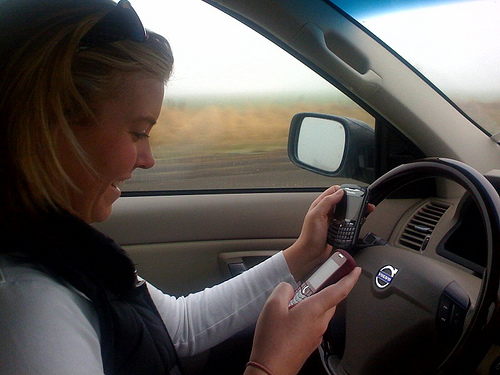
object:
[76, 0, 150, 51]
sunglasses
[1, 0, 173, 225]
head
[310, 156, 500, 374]
steering wheel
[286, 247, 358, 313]
phone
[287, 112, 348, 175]
mirror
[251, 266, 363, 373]
hand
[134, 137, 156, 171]
nose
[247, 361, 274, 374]
tie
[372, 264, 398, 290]
logo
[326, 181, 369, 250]
cell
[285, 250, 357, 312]
cell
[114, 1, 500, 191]
outside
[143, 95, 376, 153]
grass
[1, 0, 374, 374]
girl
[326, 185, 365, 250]
cellphone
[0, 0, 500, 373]
car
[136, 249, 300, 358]
long sleeve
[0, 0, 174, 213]
hair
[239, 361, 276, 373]
wrist